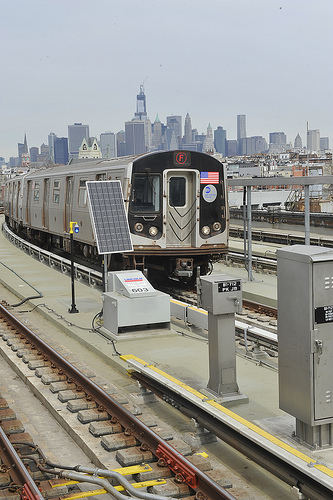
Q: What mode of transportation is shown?
A: Train.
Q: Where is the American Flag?
A: Front of the train.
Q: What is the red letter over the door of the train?
A: F.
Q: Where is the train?
A: Tracks.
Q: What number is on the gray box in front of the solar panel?
A: 603.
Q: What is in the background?
A: Buildings.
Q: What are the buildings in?
A: City.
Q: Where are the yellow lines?
A: Pavement.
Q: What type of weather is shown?
A: Overcast.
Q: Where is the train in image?
A: On tracks.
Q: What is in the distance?
A: Buildings.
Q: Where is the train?
A: On the tracks.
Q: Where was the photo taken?
A: A big city.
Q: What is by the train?
A: A solar panel.